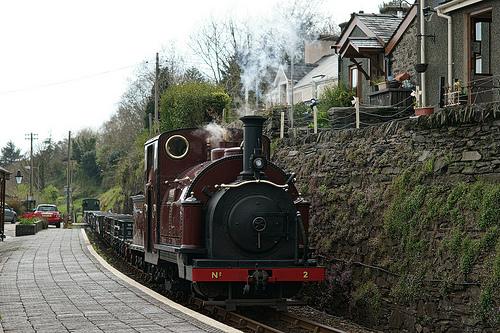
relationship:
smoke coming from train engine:
[190, 0, 324, 149] [129, 115, 326, 311]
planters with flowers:
[16, 217, 48, 236] [18, 211, 44, 224]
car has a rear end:
[33, 204, 61, 229] [34, 211, 61, 223]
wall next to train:
[269, 100, 499, 332] [82, 116, 325, 312]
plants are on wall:
[384, 157, 500, 275] [269, 100, 499, 332]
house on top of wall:
[417, 0, 499, 113] [269, 100, 499, 332]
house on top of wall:
[383, 0, 417, 90] [269, 100, 499, 332]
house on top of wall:
[330, 6, 409, 105] [269, 100, 499, 332]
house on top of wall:
[264, 53, 338, 111] [269, 100, 499, 332]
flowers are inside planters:
[18, 211, 44, 224] [16, 217, 48, 236]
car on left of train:
[33, 204, 61, 229] [82, 116, 325, 312]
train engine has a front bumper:
[129, 115, 326, 311] [185, 265, 324, 282]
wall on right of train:
[269, 100, 499, 332] [82, 116, 325, 312]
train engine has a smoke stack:
[129, 115, 326, 311] [238, 116, 268, 175]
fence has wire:
[279, 85, 419, 138] [359, 93, 416, 108]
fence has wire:
[279, 85, 419, 138] [358, 102, 416, 118]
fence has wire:
[279, 85, 419, 138] [359, 112, 415, 126]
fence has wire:
[279, 85, 419, 138] [315, 103, 354, 114]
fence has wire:
[279, 85, 419, 138] [316, 112, 356, 122]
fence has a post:
[279, 85, 419, 138] [415, 85, 420, 108]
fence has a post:
[279, 85, 419, 138] [356, 97, 360, 129]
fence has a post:
[279, 85, 419, 138] [313, 107, 318, 134]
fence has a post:
[279, 85, 419, 138] [280, 112, 285, 139]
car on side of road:
[33, 204, 61, 229] [4, 221, 63, 238]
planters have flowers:
[16, 217, 48, 236] [18, 211, 44, 224]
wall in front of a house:
[269, 100, 499, 332] [417, 0, 499, 113]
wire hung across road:
[0, 58, 156, 94] [4, 221, 63, 238]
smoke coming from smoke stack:
[190, 0, 324, 149] [238, 116, 268, 175]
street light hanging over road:
[14, 169, 23, 184] [4, 221, 63, 238]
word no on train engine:
[211, 271, 222, 279] [129, 115, 326, 311]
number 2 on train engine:
[303, 271, 309, 280] [129, 115, 326, 311]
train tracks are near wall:
[96, 232, 348, 333] [269, 100, 499, 332]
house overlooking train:
[417, 0, 499, 113] [82, 116, 325, 312]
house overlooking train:
[383, 0, 417, 90] [82, 116, 325, 312]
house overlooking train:
[330, 6, 409, 105] [82, 116, 325, 312]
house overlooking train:
[264, 53, 338, 111] [82, 116, 325, 312]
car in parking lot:
[33, 204, 61, 229] [4, 221, 63, 238]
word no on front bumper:
[211, 271, 222, 279] [185, 265, 324, 282]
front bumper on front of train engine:
[185, 265, 324, 282] [129, 115, 326, 311]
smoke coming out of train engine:
[190, 0, 324, 149] [129, 115, 326, 311]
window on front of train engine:
[165, 134, 190, 159] [129, 115, 326, 311]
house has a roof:
[330, 6, 409, 105] [335, 13, 407, 55]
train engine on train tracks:
[129, 115, 326, 311] [96, 232, 348, 333]